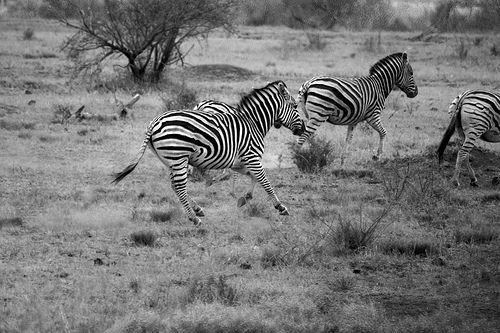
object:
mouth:
[407, 93, 419, 98]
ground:
[0, 23, 499, 331]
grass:
[2, 18, 499, 330]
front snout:
[414, 88, 419, 97]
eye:
[410, 71, 414, 75]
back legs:
[166, 167, 206, 226]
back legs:
[293, 112, 320, 170]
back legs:
[449, 130, 483, 187]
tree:
[59, 0, 233, 86]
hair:
[238, 79, 279, 108]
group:
[108, 52, 499, 227]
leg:
[367, 110, 387, 156]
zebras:
[109, 80, 307, 228]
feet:
[191, 220, 209, 228]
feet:
[274, 206, 290, 215]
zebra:
[292, 52, 417, 165]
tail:
[111, 133, 152, 185]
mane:
[369, 52, 401, 77]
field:
[5, 26, 495, 325]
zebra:
[435, 90, 500, 189]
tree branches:
[61, 26, 137, 87]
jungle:
[0, 0, 499, 333]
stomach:
[332, 103, 370, 125]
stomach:
[192, 150, 246, 167]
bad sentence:
[354, 260, 427, 294]